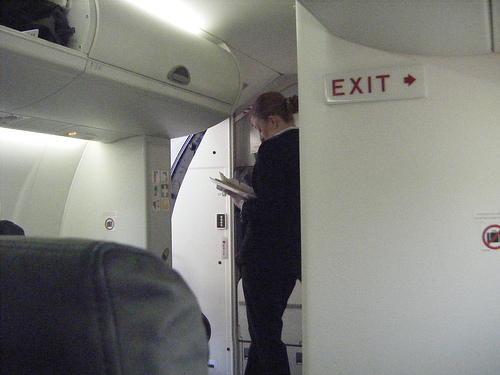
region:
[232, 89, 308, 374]
A flight attendant leaning on a wall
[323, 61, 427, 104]
A white exit sign on a wall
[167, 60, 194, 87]
A handle on an overhead compartment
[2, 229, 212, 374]
A gray seat back on a plane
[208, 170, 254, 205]
Papers in a flight attendants hand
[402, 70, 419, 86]
A red arrow on a sign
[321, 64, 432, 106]
exit indicator sign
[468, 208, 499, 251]
don't place baggage here sign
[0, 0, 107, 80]
this overhead bin is open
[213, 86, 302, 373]
this person is reading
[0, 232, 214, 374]
a headrest on the seat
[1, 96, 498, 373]
inside an airliner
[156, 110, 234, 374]
the boarding door is open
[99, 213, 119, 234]
no luggage here sign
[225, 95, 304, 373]
the person is wearing a suit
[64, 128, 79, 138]
the reading lamp is on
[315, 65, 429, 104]
A white plastic EXIT sign in red letters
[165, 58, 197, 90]
A gray oval handle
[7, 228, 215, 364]
A black leather seat edge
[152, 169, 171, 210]
A small warning sign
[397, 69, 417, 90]
A red arrow pointing right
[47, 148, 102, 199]
A white surface with a curved line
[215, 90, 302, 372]
A woman in blue looking at papers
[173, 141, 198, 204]
A curved metal bracket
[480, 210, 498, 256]
A "do not" symbol on a small sticker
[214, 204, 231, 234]
A small security panel with buttons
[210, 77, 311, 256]
the stewardess is reading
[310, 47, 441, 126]
exit sign on the wall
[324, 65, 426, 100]
the sign that says EXIT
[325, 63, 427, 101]
the word EXIT on the sign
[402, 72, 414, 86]
the arrow is small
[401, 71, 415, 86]
the small arrow is red